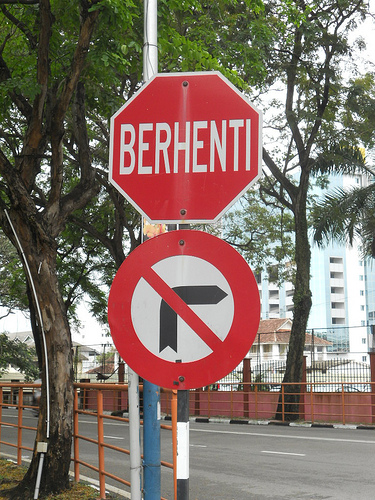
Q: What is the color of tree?
A: Brown.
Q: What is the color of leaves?
A: Green.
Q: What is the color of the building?
A: Blue.